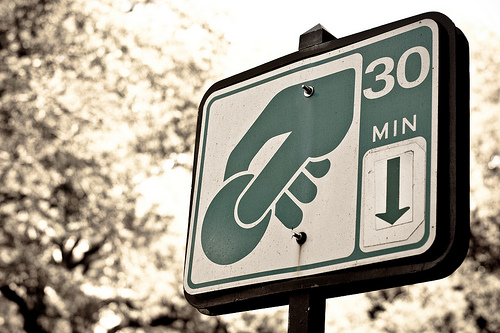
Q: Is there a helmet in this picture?
A: No, there are no helmets.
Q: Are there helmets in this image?
A: No, there are no helmets.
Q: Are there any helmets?
A: No, there are no helmets.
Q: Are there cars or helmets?
A: No, there are no helmets or cars.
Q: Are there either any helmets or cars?
A: No, there are no helmets or cars.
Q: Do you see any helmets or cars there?
A: No, there are no helmets or cars.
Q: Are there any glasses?
A: No, there are no glasses.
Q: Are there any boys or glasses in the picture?
A: No, there are no glasses or boys.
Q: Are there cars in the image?
A: No, there are no cars.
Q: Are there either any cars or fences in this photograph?
A: No, there are no cars or fences.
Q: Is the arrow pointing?
A: Yes, the arrow is pointing.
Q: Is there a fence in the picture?
A: No, there are no fences.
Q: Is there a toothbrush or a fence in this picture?
A: No, there are no fences or toothbrushes.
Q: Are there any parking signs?
A: Yes, there is a parking sign.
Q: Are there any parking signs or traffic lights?
A: Yes, there is a parking sign.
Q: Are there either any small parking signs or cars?
A: Yes, there is a small parking sign.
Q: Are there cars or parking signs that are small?
A: Yes, the parking sign is small.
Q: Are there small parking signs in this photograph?
A: Yes, there is a small parking sign.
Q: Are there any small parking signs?
A: Yes, there is a small parking sign.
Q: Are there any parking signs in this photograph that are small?
A: Yes, there is a parking sign that is small.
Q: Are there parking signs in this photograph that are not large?
A: Yes, there is a small parking sign.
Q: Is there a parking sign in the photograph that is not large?
A: Yes, there is a small parking sign.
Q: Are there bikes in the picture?
A: No, there are no bikes.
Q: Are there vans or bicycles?
A: No, there are no bicycles or vans.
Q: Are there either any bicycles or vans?
A: No, there are no bicycles or vans.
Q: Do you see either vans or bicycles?
A: No, there are no bicycles or vans.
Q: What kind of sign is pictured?
A: The sign is a parking sign.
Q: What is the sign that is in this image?
A: The sign is a parking sign.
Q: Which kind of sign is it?
A: The sign is a parking sign.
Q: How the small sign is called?
A: The sign is a parking sign.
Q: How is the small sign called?
A: The sign is a parking sign.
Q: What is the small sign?
A: The sign is a parking sign.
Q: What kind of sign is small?
A: The sign is a parking sign.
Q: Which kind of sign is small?
A: The sign is a parking sign.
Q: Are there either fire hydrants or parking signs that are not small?
A: No, there is a parking sign but it is small.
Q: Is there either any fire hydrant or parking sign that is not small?
A: No, there is a parking sign but it is small.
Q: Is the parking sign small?
A: Yes, the parking sign is small.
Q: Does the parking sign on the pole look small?
A: Yes, the parking sign is small.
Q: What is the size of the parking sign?
A: The parking sign is small.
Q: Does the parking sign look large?
A: No, the parking sign is small.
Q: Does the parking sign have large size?
A: No, the parking sign is small.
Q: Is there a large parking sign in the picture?
A: No, there is a parking sign but it is small.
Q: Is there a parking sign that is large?
A: No, there is a parking sign but it is small.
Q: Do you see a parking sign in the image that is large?
A: No, there is a parking sign but it is small.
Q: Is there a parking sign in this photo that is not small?
A: No, there is a parking sign but it is small.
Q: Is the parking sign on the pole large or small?
A: The parking sign is small.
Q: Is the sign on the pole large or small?
A: The parking sign is small.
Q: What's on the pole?
A: The parking sign is on the pole.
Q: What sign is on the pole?
A: The sign is a parking sign.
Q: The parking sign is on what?
A: The parking sign is on the pole.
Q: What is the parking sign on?
A: The parking sign is on the pole.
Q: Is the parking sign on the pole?
A: Yes, the parking sign is on the pole.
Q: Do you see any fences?
A: No, there are no fences.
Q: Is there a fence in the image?
A: No, there are no fences.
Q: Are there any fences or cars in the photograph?
A: No, there are no fences or cars.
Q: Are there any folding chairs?
A: No, there are no folding chairs.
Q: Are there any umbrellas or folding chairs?
A: No, there are no folding chairs or umbrellas.